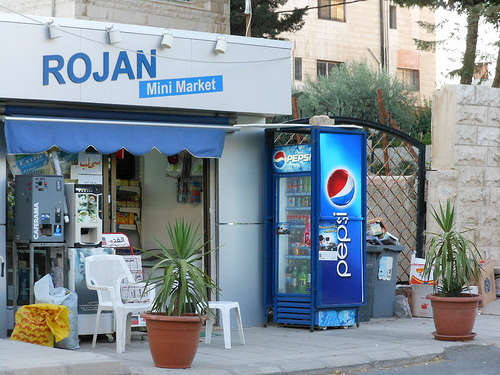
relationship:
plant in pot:
[150, 222, 210, 315] [143, 325, 200, 366]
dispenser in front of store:
[74, 226, 95, 257] [24, 152, 239, 300]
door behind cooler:
[273, 116, 427, 281] [272, 122, 370, 325]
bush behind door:
[324, 82, 352, 101] [273, 116, 427, 281]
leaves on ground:
[426, 359, 441, 367] [454, 345, 492, 362]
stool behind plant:
[92, 247, 143, 341] [150, 222, 210, 315]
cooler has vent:
[272, 122, 370, 325] [274, 307, 305, 326]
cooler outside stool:
[272, 122, 370, 325] [92, 247, 143, 341]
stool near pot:
[92, 247, 143, 341] [143, 325, 200, 366]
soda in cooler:
[290, 185, 302, 195] [272, 122, 370, 325]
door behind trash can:
[372, 181, 410, 214] [370, 222, 399, 317]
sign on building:
[160, 20, 285, 102] [392, 1, 463, 68]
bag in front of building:
[15, 301, 72, 338] [392, 1, 463, 68]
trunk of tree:
[378, 161, 402, 176] [301, 58, 412, 108]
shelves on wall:
[85, 129, 151, 151] [321, 34, 352, 46]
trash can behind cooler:
[370, 222, 399, 317] [272, 122, 370, 325]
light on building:
[201, 27, 250, 60] [392, 1, 463, 68]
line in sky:
[305, 0, 333, 12] [451, 17, 464, 23]